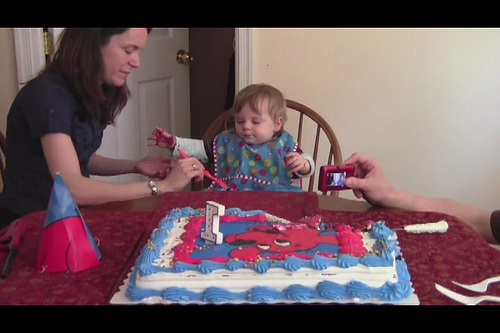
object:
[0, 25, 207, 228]
woman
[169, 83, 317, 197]
child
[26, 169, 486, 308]
birthday party